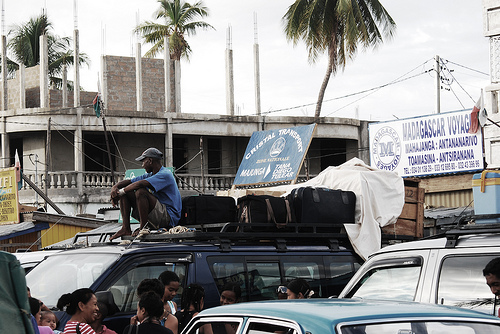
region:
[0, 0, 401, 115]
palm trees behind gray building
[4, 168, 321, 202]
balcony railing on gray building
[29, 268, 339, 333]
group of people between cars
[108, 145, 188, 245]
man sitting on car roof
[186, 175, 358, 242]
black luggage on car roof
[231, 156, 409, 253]
white sheet covering cargo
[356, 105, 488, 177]
white board with blue letters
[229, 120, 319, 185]
blue board with white letters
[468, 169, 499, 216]
blue trunk with brown edges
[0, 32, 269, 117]
gray poles on top of building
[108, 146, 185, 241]
a man sitting on a car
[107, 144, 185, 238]
a African-American man wearing a blue shirt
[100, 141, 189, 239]
a black man sitting on a car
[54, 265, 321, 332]
people standing in the street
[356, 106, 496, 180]
a sign in a foreign country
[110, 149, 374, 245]
a man transporting materials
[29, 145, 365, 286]
a man travelling on top of a vehicle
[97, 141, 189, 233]
a man waiting on the top of a car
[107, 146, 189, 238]
a man wearing a ball cap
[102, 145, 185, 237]
a man wearing a hat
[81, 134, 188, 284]
a man sitting on top of a car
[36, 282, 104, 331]
a woman with black hair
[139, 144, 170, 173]
a man wearing a hat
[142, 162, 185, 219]
a man wearing a blue shirt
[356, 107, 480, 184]
a blue and white sign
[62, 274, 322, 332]
several people standing next to a van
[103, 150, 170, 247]
a man with his knees up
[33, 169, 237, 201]
a hand rail for a balcony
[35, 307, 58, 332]
a woman holding a small child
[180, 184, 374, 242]
suitcases on top of a van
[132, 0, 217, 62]
A green palm tree.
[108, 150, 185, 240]
A man sitting on a car.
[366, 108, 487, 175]
A white and blue sign.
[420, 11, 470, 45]
Part of the sky.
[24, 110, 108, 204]
Part of a building.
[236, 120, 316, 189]
A blue and white sign.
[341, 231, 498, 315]
Part of a white car.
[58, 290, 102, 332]
A woman smiling.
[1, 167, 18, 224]
Part of a yellow sign.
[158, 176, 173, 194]
Part of a blue shirt.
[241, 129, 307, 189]
The blue sign on the car's roof.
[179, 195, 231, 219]
The black bag behind the man on the roof.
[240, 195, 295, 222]
The bag in the middle on the car's roof.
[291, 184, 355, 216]
The large black bag on the car's roof.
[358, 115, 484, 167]
The blue and white sign on the right.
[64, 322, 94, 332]
The red and white shirt the lady is wearing.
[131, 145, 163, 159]
The hat the man is wearing.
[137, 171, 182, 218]
The blue shirt the man is wearing.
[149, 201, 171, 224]
The shorts the man is wearing.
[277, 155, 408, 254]
The white blanket behind the suitcases on the car's roof.